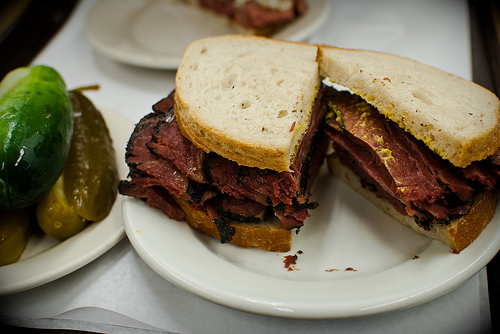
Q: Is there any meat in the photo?
A: Yes, there is meat.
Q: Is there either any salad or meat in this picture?
A: Yes, there is meat.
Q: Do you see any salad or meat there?
A: Yes, there is meat.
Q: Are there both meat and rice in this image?
A: No, there is meat but no rice.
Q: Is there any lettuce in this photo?
A: No, there is no lettuce.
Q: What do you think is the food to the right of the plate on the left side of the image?
A: The food is meat.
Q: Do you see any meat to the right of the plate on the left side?
A: Yes, there is meat to the right of the plate.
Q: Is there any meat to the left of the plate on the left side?
A: No, the meat is to the right of the plate.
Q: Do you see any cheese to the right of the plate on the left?
A: No, there is meat to the right of the plate.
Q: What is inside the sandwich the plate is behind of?
A: The meat is inside the sandwich.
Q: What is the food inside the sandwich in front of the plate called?
A: The food is meat.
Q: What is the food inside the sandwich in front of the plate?
A: The food is meat.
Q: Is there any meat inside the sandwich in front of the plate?
A: Yes, there is meat inside the sandwich.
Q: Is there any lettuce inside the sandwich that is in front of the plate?
A: No, there is meat inside the sandwich.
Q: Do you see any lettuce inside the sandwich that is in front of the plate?
A: No, there is meat inside the sandwich.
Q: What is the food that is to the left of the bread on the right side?
A: The food is meat.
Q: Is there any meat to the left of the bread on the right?
A: Yes, there is meat to the left of the bread.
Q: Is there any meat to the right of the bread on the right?
A: No, the meat is to the left of the bread.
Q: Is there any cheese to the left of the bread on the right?
A: No, there is meat to the left of the bread.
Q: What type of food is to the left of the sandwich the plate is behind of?
A: The food is meat.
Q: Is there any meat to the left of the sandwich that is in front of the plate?
A: Yes, there is meat to the left of the sandwich.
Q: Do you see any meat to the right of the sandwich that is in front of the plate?
A: No, the meat is to the left of the sandwich.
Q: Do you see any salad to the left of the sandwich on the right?
A: No, there is meat to the left of the sandwich.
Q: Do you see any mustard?
A: Yes, there is mustard.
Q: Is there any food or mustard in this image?
A: Yes, there is mustard.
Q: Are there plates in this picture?
A: Yes, there is a plate.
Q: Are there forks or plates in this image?
A: Yes, there is a plate.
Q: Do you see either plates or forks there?
A: Yes, there is a plate.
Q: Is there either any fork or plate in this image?
A: Yes, there is a plate.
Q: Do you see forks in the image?
A: No, there are no forks.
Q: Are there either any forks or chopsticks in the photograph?
A: No, there are no forks or chopsticks.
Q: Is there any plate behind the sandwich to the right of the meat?
A: Yes, there is a plate behind the sandwich.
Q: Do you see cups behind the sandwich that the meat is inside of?
A: No, there is a plate behind the sandwich.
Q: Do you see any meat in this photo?
A: Yes, there is meat.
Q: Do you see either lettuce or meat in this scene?
A: Yes, there is meat.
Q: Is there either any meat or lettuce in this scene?
A: Yes, there is meat.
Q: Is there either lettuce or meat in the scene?
A: Yes, there is meat.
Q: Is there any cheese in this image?
A: No, there is no cheese.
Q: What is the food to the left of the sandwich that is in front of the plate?
A: The food is meat.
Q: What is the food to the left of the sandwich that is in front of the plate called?
A: The food is meat.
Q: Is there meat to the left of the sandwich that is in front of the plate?
A: Yes, there is meat to the left of the sandwich.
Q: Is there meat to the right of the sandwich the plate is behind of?
A: No, the meat is to the left of the sandwich.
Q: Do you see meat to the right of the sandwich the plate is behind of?
A: No, the meat is to the left of the sandwich.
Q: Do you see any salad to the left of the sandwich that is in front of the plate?
A: No, there is meat to the left of the sandwich.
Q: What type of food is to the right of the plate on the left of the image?
A: The food is meat.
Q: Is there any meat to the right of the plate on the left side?
A: Yes, there is meat to the right of the plate.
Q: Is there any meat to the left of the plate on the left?
A: No, the meat is to the right of the plate.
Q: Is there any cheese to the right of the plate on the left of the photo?
A: No, there is meat to the right of the plate.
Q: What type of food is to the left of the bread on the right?
A: The food is meat.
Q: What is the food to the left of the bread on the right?
A: The food is meat.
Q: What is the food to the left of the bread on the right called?
A: The food is meat.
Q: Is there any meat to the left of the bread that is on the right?
A: Yes, there is meat to the left of the bread.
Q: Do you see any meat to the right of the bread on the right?
A: No, the meat is to the left of the bread.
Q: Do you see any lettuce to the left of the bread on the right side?
A: No, there is meat to the left of the bread.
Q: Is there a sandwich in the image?
A: Yes, there is a sandwich.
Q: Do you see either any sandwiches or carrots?
A: Yes, there is a sandwich.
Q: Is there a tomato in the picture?
A: No, there are no tomatoes.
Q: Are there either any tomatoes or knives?
A: No, there are no tomatoes or knives.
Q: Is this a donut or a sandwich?
A: This is a sandwich.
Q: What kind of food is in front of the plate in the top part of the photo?
A: The food is a sandwich.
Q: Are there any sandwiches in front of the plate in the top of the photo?
A: Yes, there is a sandwich in front of the plate.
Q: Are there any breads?
A: Yes, there is a bread.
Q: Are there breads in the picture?
A: Yes, there is a bread.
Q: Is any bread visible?
A: Yes, there is a bread.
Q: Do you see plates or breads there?
A: Yes, there is a bread.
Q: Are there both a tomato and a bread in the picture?
A: No, there is a bread but no tomatoes.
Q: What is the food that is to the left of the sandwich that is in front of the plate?
A: The food is a bread.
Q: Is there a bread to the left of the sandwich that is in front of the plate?
A: Yes, there is a bread to the left of the sandwich.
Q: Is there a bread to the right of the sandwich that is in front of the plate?
A: No, the bread is to the left of the sandwich.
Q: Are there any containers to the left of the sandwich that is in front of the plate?
A: No, there is a bread to the left of the sandwich.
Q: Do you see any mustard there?
A: Yes, there is mustard.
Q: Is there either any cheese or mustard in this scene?
A: Yes, there is mustard.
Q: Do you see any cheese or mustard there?
A: Yes, there is mustard.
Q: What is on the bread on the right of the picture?
A: The mustard is on the bread.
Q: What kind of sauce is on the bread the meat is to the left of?
A: The sauce is mustard.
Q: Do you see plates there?
A: Yes, there is a plate.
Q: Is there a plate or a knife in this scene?
A: Yes, there is a plate.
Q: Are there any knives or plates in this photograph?
A: Yes, there is a plate.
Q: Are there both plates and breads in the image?
A: Yes, there are both a plate and a bread.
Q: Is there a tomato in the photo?
A: No, there are no tomatoes.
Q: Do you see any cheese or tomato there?
A: No, there are no tomatoes or cheese.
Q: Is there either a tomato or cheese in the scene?
A: No, there are no tomatoes or cheese.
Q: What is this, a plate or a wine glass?
A: This is a plate.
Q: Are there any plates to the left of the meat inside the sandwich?
A: Yes, there is a plate to the left of the meat.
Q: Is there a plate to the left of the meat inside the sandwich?
A: Yes, there is a plate to the left of the meat.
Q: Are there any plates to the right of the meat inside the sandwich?
A: No, the plate is to the left of the meat.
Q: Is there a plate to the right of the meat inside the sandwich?
A: No, the plate is to the left of the meat.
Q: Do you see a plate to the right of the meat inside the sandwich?
A: No, the plate is to the left of the meat.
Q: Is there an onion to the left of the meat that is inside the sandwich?
A: No, there is a plate to the left of the meat.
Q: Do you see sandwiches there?
A: Yes, there is a sandwich.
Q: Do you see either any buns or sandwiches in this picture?
A: Yes, there is a sandwich.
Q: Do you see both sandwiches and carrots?
A: No, there is a sandwich but no carrots.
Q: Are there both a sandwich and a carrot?
A: No, there is a sandwich but no carrots.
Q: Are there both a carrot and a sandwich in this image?
A: No, there is a sandwich but no carrots.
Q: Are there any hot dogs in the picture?
A: No, there are no hot dogs.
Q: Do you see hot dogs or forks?
A: No, there are no hot dogs or forks.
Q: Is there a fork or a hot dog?
A: No, there are no hot dogs or forks.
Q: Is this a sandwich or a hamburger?
A: This is a sandwich.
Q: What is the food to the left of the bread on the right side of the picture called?
A: The food is a sandwich.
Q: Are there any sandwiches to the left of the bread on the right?
A: Yes, there is a sandwich to the left of the bread.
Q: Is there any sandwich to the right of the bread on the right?
A: No, the sandwich is to the left of the bread.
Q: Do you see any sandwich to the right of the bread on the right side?
A: No, the sandwich is to the left of the bread.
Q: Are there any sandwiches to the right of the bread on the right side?
A: No, the sandwich is to the left of the bread.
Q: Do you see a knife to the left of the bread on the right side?
A: No, there is a sandwich to the left of the bread.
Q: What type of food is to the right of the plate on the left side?
A: The food is a sandwich.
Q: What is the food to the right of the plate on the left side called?
A: The food is a sandwich.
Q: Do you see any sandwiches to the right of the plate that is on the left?
A: Yes, there is a sandwich to the right of the plate.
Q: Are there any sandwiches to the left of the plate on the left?
A: No, the sandwich is to the right of the plate.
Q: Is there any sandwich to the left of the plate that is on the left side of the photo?
A: No, the sandwich is to the right of the plate.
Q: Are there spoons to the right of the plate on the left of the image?
A: No, there is a sandwich to the right of the plate.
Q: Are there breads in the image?
A: Yes, there is a bread.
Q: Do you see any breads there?
A: Yes, there is a bread.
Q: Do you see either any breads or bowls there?
A: Yes, there is a bread.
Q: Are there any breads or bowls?
A: Yes, there is a bread.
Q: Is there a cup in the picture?
A: No, there are no cups.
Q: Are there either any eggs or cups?
A: No, there are no cups or eggs.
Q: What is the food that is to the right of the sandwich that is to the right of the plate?
A: The food is a bread.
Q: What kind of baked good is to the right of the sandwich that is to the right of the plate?
A: The food is a bread.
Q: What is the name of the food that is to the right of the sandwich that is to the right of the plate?
A: The food is a bread.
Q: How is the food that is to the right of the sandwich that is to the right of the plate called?
A: The food is a bread.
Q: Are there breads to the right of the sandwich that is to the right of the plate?
A: Yes, there is a bread to the right of the sandwich.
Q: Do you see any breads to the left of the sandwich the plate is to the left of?
A: No, the bread is to the right of the sandwich.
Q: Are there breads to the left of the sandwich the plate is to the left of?
A: No, the bread is to the right of the sandwich.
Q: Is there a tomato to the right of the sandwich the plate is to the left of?
A: No, there is a bread to the right of the sandwich.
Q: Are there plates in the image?
A: Yes, there is a plate.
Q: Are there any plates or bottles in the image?
A: Yes, there is a plate.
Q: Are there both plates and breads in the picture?
A: Yes, there are both a plate and a bread.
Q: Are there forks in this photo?
A: No, there are no forks.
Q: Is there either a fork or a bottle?
A: No, there are no forks or bottles.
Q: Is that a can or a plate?
A: That is a plate.